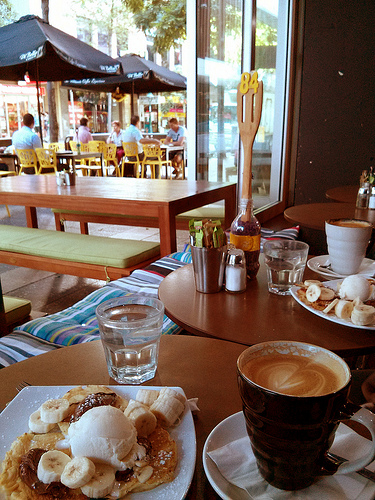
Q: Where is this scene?
A: A cafe.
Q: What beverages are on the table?
A: Lattes and water.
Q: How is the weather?
A: Sunny.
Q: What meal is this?
A: Breakfast.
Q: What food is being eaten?
A: Pancakes.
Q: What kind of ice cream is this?
A: Vanilla.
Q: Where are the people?
A: Under the umbrellas.